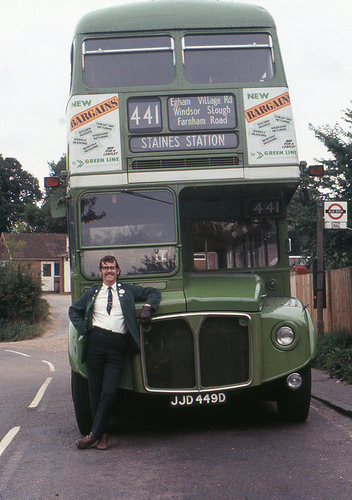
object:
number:
[126, 98, 160, 132]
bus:
[44, 0, 324, 438]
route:
[138, 130, 230, 150]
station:
[169, 92, 242, 129]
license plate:
[168, 391, 226, 406]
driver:
[68, 254, 161, 450]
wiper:
[124, 188, 173, 204]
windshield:
[79, 187, 179, 279]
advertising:
[65, 89, 120, 183]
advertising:
[243, 83, 296, 166]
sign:
[323, 200, 348, 231]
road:
[0, 293, 350, 500]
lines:
[0, 422, 19, 455]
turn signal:
[43, 175, 60, 187]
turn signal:
[304, 164, 323, 178]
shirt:
[92, 282, 129, 334]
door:
[39, 260, 58, 294]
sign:
[123, 94, 246, 159]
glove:
[140, 305, 151, 324]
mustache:
[103, 267, 121, 279]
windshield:
[79, 35, 175, 90]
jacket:
[68, 282, 160, 364]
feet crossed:
[75, 435, 105, 449]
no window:
[174, 178, 299, 279]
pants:
[84, 324, 126, 442]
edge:
[37, 374, 56, 407]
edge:
[65, 38, 86, 459]